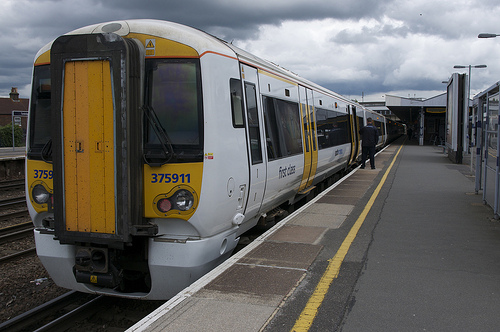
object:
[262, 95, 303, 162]
window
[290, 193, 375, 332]
yellow line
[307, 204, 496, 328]
floor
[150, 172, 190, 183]
375911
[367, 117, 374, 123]
head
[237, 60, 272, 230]
white door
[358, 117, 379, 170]
man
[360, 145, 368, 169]
leg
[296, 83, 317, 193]
double doors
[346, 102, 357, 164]
double doors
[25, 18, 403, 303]
train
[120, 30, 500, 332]
station